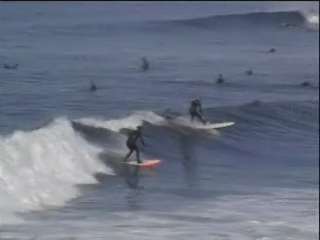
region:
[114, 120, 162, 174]
Surfer on ocean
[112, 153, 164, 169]
Surfboard is orange and white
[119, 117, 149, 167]
Surfer wears black suit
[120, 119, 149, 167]
Surfer bend forward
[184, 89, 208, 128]
Surfer on a wave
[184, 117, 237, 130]
Surfboard is white and large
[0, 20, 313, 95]
People in the sea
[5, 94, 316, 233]
Wave is rolling in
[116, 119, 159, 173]
Person stand with legs extended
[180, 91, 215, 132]
Extended legs of surfer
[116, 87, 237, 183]
two peoples on surfboard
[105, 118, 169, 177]
person on orange surf board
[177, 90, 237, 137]
person on white surf board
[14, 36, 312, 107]
many people in water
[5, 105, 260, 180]
two people riding waves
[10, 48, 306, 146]
people wading in water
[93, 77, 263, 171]
two competitors surfing on boards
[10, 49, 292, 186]
people surfing in ocean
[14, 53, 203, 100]
people waiting for waves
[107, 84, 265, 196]
person on board with orange ahead of other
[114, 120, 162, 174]
a person surfing in water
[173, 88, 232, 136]
a person surfing in water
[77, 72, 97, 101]
a person in water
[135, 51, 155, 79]
a person in water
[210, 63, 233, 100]
a person in water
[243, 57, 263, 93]
a person in water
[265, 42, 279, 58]
a person in water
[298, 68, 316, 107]
a person in water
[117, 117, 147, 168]
a person in water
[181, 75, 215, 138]
a person in water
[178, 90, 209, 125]
a person in water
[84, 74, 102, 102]
a person in water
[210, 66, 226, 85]
a person in water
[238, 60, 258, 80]
a person in water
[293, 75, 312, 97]
a person in water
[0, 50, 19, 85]
a person in water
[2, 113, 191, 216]
a wave in an ocean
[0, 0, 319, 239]
a blue section of ocean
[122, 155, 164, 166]
a white and red surfboard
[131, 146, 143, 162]
the leg of a man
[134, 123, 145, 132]
the head of a man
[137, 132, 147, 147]
the arm of a man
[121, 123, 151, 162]
a black wet suit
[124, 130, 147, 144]
the torso of the man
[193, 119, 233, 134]
a white surfboard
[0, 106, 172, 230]
the white crest of a wave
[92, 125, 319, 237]
calm water in front of the surfers